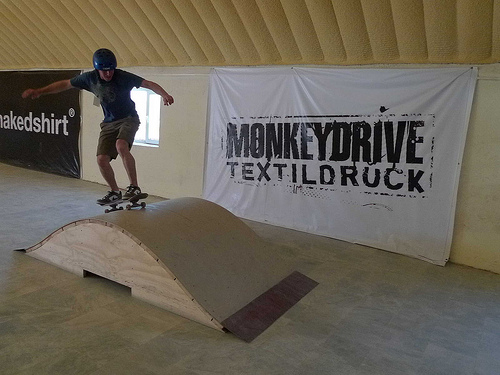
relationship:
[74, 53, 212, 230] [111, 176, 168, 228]
man riding skateboard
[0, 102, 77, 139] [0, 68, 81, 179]
letters on a signboard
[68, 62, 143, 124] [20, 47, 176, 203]
t-shirt on skateboarder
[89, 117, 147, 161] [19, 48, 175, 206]
brown pants on man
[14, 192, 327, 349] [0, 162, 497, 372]
ramp on concrete floor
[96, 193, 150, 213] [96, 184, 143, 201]
skateboard under feet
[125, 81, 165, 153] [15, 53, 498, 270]
window in wall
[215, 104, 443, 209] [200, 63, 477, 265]
writing on sign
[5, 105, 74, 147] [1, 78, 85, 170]
lettering on sign